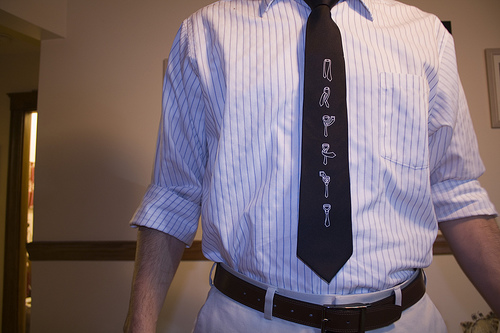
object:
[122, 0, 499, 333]
man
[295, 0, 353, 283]
tie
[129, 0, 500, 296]
shirt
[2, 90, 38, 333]
door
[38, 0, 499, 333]
wall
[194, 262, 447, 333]
pants